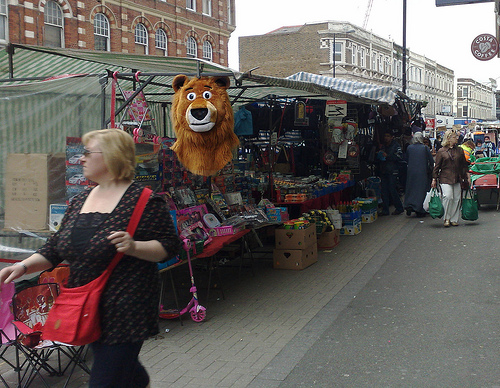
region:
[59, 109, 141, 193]
head of a person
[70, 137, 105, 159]
eye of a person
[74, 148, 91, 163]
nose of a person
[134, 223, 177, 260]
arm of a person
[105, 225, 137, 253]
hand of a person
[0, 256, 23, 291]
hand of a person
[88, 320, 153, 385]
leg of a person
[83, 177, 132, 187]
neck of a person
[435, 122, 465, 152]
head of a person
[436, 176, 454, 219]
leg of a person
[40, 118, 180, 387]
Woman wearing black pants.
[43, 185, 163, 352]
Red purse being carried by a woman.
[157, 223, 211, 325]
Pink scooter at toy booth.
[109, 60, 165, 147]
Pink and white stroller hanging from tent.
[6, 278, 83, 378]
Red, black and white child's folding chair.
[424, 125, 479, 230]
Woman carrying two green bags.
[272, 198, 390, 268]
Boxes of goods on ground in front of tables.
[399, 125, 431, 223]
Woman wearing a long blue coat.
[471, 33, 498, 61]
A coffee sign with coffee beans in center.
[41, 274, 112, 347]
A red handbag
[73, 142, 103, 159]
Glasses on the eyes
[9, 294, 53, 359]
A chair in the photo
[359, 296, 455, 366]
A road with tarmac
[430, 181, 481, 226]
Green bags in the hands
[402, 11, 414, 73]
A pole in the picture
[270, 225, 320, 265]
Boxes in the photo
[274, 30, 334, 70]
Buiding in the background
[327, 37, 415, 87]
Windows on the building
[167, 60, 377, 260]
merch tent on sidewalk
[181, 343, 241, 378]
bricks on the walkway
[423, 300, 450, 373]
asphalt on the ground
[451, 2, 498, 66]
the sign is hanging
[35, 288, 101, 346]
the bag is red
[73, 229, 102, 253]
pattern on the shirt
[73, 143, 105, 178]
face of the woman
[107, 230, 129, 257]
hand of the woman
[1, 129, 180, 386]
Woman wearing a red purse.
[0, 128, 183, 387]
Woman wearing dark pants.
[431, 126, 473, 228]
Woman holding green bags.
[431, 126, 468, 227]
Woman wearing white pants.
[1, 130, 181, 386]
Woman wearing glasses.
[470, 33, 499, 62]
Round sign.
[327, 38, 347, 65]
Window of a building.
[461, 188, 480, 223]
Green bag with handles.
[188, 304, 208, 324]
Pink wheel on a scooter.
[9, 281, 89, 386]
Red folding chair on the ground.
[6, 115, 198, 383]
large woman with red bag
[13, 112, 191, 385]
large woman with red bag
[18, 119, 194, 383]
large woman with red bag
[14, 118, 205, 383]
large woman with red bag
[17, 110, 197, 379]
large woman with red bag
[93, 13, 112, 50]
a window on a building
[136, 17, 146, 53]
a window on a building